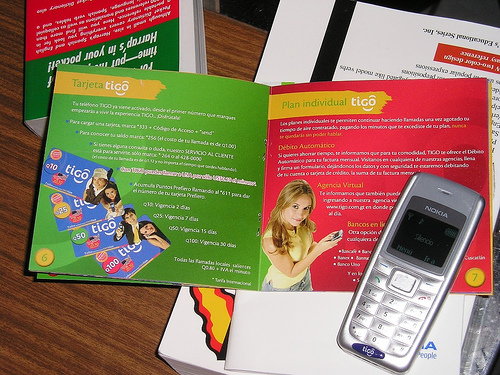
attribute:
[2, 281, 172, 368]
table top — wooden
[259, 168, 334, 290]
lady — blonde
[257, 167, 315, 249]
hair — long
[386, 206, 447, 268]
phone — on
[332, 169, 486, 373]
phone — gray, Nokia, mobile phone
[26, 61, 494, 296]
booklet — plans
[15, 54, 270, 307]
page — green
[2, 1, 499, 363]
desk — wood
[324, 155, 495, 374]
cellphone — silver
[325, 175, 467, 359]
mobile phone — nokia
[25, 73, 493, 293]
book — open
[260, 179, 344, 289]
woman — holding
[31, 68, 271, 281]
phone plan — individual